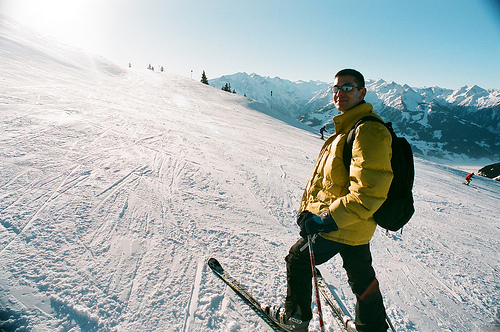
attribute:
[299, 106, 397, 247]
jacket — puffy, yellow